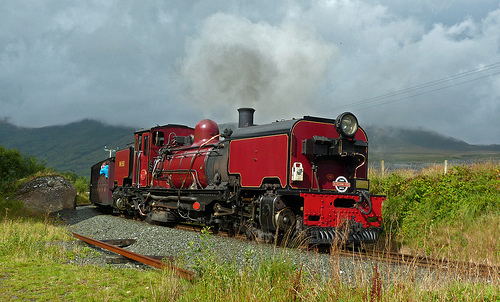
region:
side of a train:
[222, 147, 300, 226]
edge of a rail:
[168, 219, 213, 244]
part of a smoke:
[221, 55, 294, 123]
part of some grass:
[170, 264, 212, 297]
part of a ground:
[165, 225, 203, 255]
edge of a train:
[256, 108, 306, 210]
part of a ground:
[187, 226, 233, 266]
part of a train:
[305, 168, 355, 259]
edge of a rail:
[193, 224, 224, 237]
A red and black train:
[129, 100, 396, 257]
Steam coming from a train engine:
[191, 15, 295, 152]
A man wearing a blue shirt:
[96, 156, 113, 184]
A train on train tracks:
[290, 182, 485, 277]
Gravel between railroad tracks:
[73, 212, 194, 284]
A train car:
[80, 147, 116, 211]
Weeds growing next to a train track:
[189, 224, 432, 299]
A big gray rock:
[13, 169, 82, 217]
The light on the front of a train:
[331, 107, 367, 147]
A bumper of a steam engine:
[297, 212, 389, 252]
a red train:
[83, 139, 368, 243]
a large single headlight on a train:
[327, 98, 364, 153]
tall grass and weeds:
[172, 203, 488, 299]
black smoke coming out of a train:
[187, 13, 296, 115]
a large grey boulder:
[16, 156, 74, 229]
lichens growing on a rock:
[12, 166, 69, 193]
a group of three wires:
[345, 43, 494, 121]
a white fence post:
[437, 140, 452, 183]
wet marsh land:
[380, 143, 431, 173]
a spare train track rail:
[57, 215, 199, 285]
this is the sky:
[26, 31, 126, 77]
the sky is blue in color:
[425, 17, 433, 28]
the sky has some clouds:
[16, 27, 140, 84]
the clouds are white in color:
[373, 27, 462, 82]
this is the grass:
[413, 165, 467, 245]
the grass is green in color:
[408, 194, 436, 211]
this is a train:
[93, 106, 388, 244]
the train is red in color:
[266, 139, 288, 166]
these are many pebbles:
[143, 226, 168, 246]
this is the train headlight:
[331, 115, 358, 136]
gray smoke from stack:
[224, 57, 274, 120]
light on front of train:
[334, 108, 361, 141]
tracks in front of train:
[370, 246, 432, 269]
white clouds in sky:
[412, 20, 486, 65]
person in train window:
[95, 155, 115, 184]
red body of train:
[134, 132, 299, 194]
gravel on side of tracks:
[147, 223, 182, 252]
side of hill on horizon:
[36, 117, 98, 152]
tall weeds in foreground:
[217, 254, 297, 299]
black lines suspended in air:
[428, 65, 487, 99]